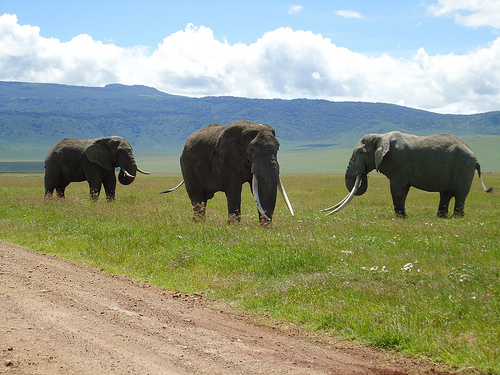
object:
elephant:
[35, 126, 156, 207]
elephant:
[159, 115, 304, 233]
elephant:
[314, 126, 500, 226]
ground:
[1, 156, 500, 374]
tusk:
[121, 168, 137, 180]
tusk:
[136, 168, 152, 176]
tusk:
[250, 173, 273, 222]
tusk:
[274, 173, 298, 220]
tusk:
[323, 175, 361, 219]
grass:
[0, 158, 500, 373]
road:
[0, 239, 500, 375]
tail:
[157, 178, 186, 198]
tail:
[474, 162, 497, 195]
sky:
[0, 1, 497, 114]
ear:
[81, 135, 120, 171]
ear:
[210, 121, 251, 182]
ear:
[363, 130, 397, 173]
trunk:
[116, 165, 138, 188]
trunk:
[250, 157, 284, 231]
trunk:
[343, 151, 370, 197]